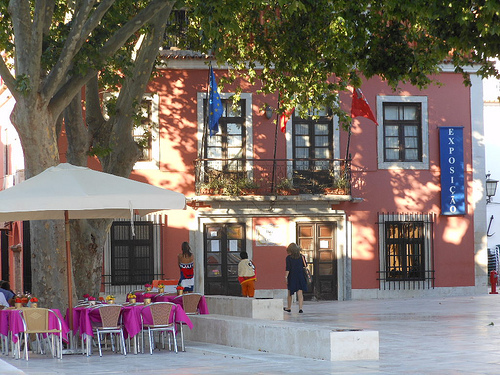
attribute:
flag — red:
[344, 72, 374, 128]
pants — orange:
[234, 273, 258, 297]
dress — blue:
[287, 252, 307, 292]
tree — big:
[2, 0, 498, 315]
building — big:
[0, 50, 486, 300]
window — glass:
[384, 99, 422, 157]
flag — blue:
[201, 55, 235, 145]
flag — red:
[350, 78, 376, 133]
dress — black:
[280, 257, 308, 293]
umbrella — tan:
[2, 155, 184, 221]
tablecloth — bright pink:
[69, 305, 143, 338]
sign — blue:
[434, 115, 474, 227]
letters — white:
[444, 128, 459, 211]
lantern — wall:
[478, 168, 497, 212]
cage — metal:
[377, 208, 437, 289]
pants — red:
[237, 276, 256, 297]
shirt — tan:
[235, 261, 255, 281]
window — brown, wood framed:
[384, 98, 429, 169]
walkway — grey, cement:
[299, 304, 499, 372]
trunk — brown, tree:
[3, 45, 93, 321]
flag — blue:
[204, 59, 224, 135]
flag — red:
[343, 81, 382, 129]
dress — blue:
[281, 260, 310, 290]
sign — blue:
[435, 119, 473, 220]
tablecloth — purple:
[65, 303, 141, 334]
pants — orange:
[234, 272, 262, 300]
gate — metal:
[374, 206, 440, 296]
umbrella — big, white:
[7, 156, 207, 227]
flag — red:
[338, 73, 381, 136]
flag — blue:
[199, 62, 236, 142]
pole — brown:
[57, 206, 89, 328]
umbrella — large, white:
[4, 145, 210, 243]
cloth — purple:
[44, 307, 66, 339]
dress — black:
[276, 250, 316, 300]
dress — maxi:
[284, 249, 310, 294]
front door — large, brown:
[292, 214, 344, 308]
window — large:
[277, 73, 356, 202]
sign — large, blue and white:
[429, 119, 473, 231]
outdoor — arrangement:
[4, 264, 202, 363]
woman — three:
[151, 226, 339, 316]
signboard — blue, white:
[428, 120, 490, 227]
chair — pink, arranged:
[28, 284, 207, 341]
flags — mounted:
[159, 57, 389, 179]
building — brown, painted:
[108, 43, 494, 365]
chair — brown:
[141, 295, 191, 335]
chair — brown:
[86, 298, 145, 351]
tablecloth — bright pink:
[122, 297, 161, 332]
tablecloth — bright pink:
[129, 294, 209, 329]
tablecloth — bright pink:
[1, 302, 112, 359]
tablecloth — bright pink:
[164, 294, 235, 321]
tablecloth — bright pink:
[113, 281, 167, 301]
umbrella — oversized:
[2, 150, 175, 240]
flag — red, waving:
[331, 81, 398, 144]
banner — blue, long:
[423, 117, 483, 217]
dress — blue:
[276, 250, 319, 280]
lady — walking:
[278, 249, 317, 309]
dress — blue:
[276, 254, 306, 278]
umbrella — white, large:
[12, 153, 218, 240]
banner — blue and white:
[437, 123, 472, 216]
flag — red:
[271, 85, 299, 138]